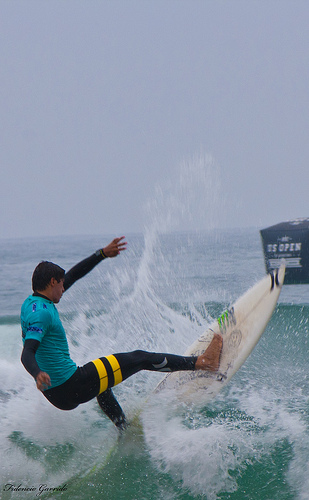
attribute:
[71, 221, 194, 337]
splush — white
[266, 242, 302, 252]
text — white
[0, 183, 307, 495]
waves — white, large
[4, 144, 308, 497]
foam — white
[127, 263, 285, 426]
surfboard — white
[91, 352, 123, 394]
stripe — yellow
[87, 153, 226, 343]
water — white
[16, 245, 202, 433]
swim suit — fitting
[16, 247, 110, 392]
shirt — blue 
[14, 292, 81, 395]
shirt — teal, blue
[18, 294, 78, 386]
t-shirt — blue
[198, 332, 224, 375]
foot — bare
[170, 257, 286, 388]
board — surf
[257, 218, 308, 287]
box — blue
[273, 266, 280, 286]
stripes — black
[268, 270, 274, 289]
stripes — black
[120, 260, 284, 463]
surfboard — white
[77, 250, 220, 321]
water — white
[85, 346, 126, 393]
line — large, yellow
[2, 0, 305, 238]
sky — grey 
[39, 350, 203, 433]
pants — black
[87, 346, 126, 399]
stripes — yellow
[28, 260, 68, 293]
hair — black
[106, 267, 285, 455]
surfboard — white